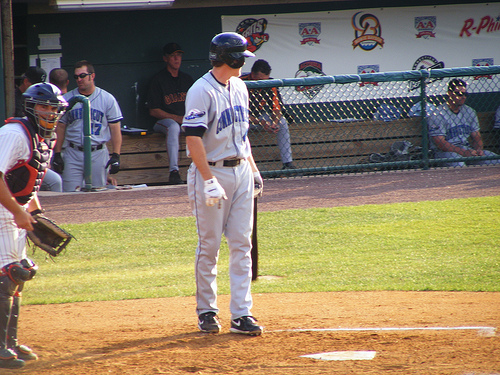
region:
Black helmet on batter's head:
[195, 27, 259, 91]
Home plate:
[298, 339, 390, 367]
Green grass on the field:
[325, 218, 462, 292]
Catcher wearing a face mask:
[15, 77, 76, 181]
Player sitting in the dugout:
[404, 62, 496, 175]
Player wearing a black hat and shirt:
[131, 41, 205, 127]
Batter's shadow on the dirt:
[75, 325, 235, 364]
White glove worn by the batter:
[196, 160, 234, 216]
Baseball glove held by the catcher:
[8, 196, 80, 265]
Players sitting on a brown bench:
[133, 38, 489, 171]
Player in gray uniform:
[185, 29, 267, 337]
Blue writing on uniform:
[209, 92, 248, 146]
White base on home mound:
[299, 341, 380, 372]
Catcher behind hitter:
[2, 67, 75, 362]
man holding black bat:
[179, 23, 270, 335]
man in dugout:
[63, 66, 125, 189]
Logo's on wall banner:
[222, 8, 498, 108]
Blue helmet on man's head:
[208, 23, 258, 78]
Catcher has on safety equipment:
[4, 66, 69, 367]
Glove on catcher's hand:
[14, 211, 71, 261]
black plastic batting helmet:
[208, 30, 254, 61]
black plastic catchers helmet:
[23, 83, 66, 130]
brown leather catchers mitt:
[28, 211, 73, 257]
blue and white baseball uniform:
[185, 70, 259, 321]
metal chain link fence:
[244, 66, 498, 173]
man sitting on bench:
[149, 46, 196, 171]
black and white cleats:
[198, 310, 259, 334]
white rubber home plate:
[306, 347, 378, 364]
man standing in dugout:
[63, 66, 124, 188]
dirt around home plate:
[24, 301, 497, 373]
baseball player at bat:
[152, 20, 320, 351]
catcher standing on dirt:
[4, 81, 87, 374]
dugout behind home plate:
[168, 41, 408, 372]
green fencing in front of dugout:
[269, 71, 476, 199]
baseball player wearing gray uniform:
[172, 30, 307, 221]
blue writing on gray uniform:
[186, 81, 286, 178]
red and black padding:
[4, 110, 65, 227]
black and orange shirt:
[132, 65, 200, 125]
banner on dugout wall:
[266, 9, 471, 116]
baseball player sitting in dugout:
[365, 81, 495, 178]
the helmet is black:
[215, 27, 262, 74]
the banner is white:
[215, 12, 499, 85]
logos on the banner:
[240, 18, 484, 73]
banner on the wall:
[219, 12, 499, 44]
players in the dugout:
[40, 66, 317, 166]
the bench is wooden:
[111, 127, 388, 170]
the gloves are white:
[195, 172, 262, 202]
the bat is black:
[247, 194, 259, 279]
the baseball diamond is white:
[307, 338, 389, 373]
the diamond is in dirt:
[301, 340, 393, 372]